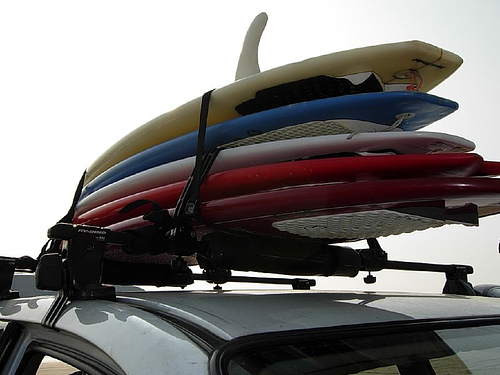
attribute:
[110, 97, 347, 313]
surfboards — blue, white, red, yellow, strapped, here, stacked, wine, atop, mounted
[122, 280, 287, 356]
car — strong, hauling, gray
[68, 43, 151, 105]
sky — colored, blue, beautiful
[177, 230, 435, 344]
rack — black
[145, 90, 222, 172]
strap — holding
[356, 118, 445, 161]
string — white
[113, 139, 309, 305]
luggage — here, placed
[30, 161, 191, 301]
objects — placed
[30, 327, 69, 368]
door — back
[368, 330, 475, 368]
glass — back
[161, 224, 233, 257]
tube — rubber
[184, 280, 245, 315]
bolt — ontop